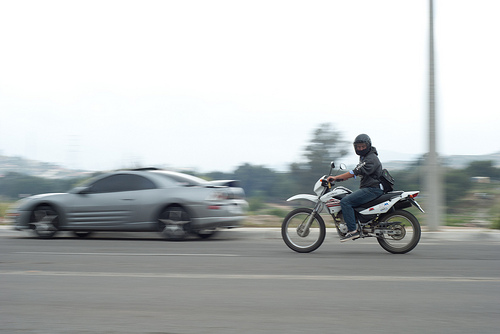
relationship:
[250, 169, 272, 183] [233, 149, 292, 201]
leaves on tree